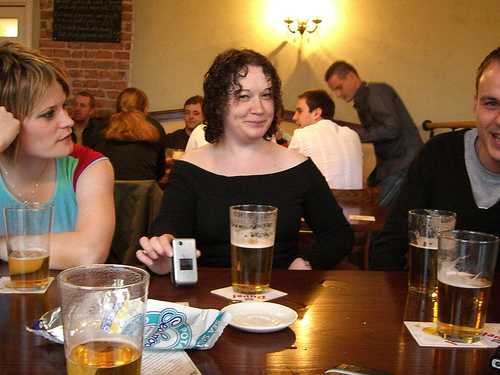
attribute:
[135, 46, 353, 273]
woman — White 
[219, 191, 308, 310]
cup — clear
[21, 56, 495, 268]
people — several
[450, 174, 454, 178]
ground — black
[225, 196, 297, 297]
cup — clear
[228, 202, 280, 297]
glass — clear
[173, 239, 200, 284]
phone — small, mobile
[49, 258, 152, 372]
cup — Clear 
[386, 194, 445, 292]
glass — clear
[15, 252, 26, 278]
liquid — Brown 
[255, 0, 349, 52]
bulbs — lit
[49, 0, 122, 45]
blackboard — black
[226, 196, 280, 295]
glass — clear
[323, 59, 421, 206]
people — gathered around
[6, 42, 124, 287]
woman — Blonde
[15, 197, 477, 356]
cups — some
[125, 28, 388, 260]
person — sitting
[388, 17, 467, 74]
wall — yellow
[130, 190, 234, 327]
cell phone — White 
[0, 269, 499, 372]
table — brown, wooden, Clear 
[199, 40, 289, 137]
hair — girl's